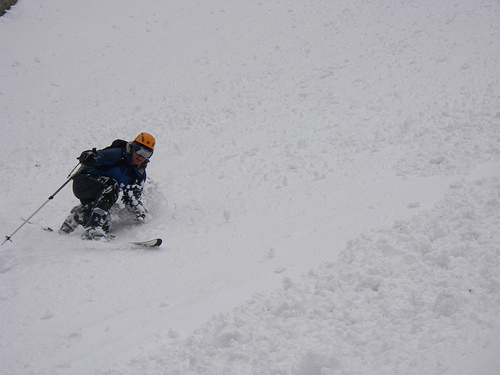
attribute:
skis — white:
[58, 222, 219, 275]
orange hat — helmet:
[120, 122, 167, 156]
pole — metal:
[35, 144, 126, 217]